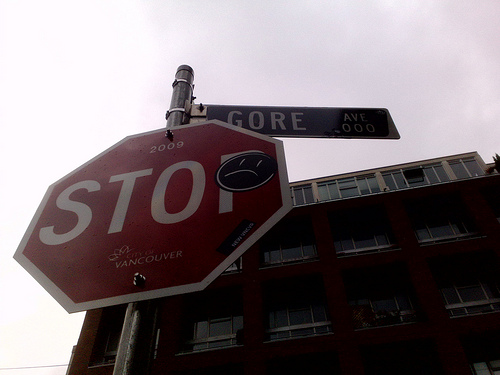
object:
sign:
[13, 117, 296, 314]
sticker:
[216, 153, 279, 192]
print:
[36, 150, 276, 246]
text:
[114, 249, 182, 269]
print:
[150, 140, 184, 156]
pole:
[107, 64, 193, 375]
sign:
[207, 104, 401, 139]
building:
[60, 151, 500, 374]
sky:
[1, 0, 498, 375]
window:
[367, 176, 382, 197]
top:
[166, 64, 193, 126]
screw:
[165, 129, 173, 139]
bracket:
[166, 107, 188, 118]